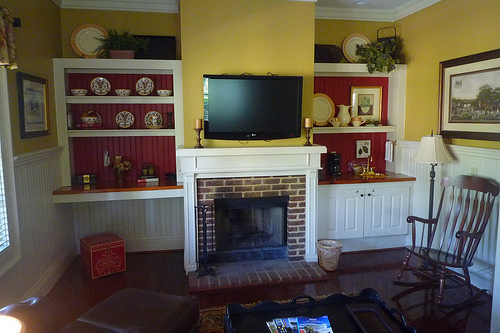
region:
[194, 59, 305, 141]
Flat screen TV on yellow wall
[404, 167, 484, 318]
Brown rocking chair against wall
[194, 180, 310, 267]
Brick fire place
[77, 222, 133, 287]
Red and gold box on floor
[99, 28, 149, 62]
Plant on top shelf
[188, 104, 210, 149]
Candle stick on fireplace mantle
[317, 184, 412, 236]
White cabinet doors by fireplace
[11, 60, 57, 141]
Picture on yellow wall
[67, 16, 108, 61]
Yellow and white plate on top shelf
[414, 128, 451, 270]
Tall lamp beside rocking chair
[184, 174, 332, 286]
brick fireplace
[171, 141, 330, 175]
white fireplace mantle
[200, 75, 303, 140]
flat screen tv above fireplace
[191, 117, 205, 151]
golden candle on mantle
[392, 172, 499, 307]
wooden rocking chair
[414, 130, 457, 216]
beige colored lamp with wood base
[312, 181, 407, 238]
white cabinets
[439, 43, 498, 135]
framed landscape painting on the wall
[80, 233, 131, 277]
red and gold box under shelf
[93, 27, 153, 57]
green plant in a brown box on top shelf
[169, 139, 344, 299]
Brick fireplace with white mantlepiece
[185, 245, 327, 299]
Red brick hearth on fireplace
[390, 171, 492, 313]
Wooden rocking chair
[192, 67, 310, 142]
Television mounted on the wall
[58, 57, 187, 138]
Decorative plates and bowls on shelves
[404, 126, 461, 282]
Floor lamp with white shade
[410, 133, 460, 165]
White lamp shade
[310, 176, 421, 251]
White cabinet doors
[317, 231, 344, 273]
Small waste basket with plastic liner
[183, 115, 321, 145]
Candles on a mantlepiece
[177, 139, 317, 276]
SMALL BRICK FIREPLACE IN LIVING ROOM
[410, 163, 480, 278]
BROWN WOODEN ROCKING CHAIR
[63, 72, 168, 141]
ASSORTED DISPLAY PLATES ON SHELF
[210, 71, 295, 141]
BLACK FLAT SCREEN TV ON WALL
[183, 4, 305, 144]
YELLOW WALL ABOVE FIREPLACE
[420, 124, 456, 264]
TAN ORNATE LAMP BY WALL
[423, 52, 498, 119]
NATURE PAINTING HUNG ON WALL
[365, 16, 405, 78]
SMALL BASKET ABOVE SHELF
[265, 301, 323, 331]
GROUP OF BLUE MAGAZINES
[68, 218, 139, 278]
SMALL RED AND YELLOW BOX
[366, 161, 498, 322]
wood rocking chair on floor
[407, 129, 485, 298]
lamp standing next to rocking chair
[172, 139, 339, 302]
white mantel over brick fireplace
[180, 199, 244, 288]
black tools for fireplace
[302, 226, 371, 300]
waste basket next to mantel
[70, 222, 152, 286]
red and white box on floor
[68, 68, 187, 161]
decorative dishes on shelves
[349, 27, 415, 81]
green plant on shelf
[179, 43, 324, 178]
television on wall over mantel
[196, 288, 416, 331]
coffee table with magazines